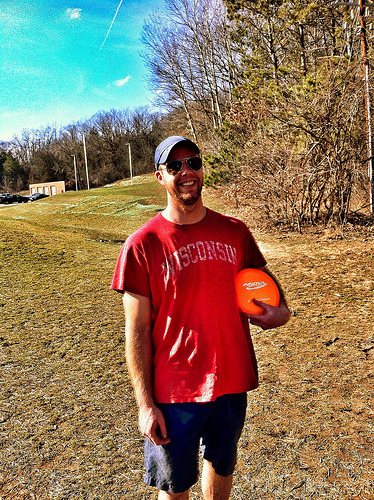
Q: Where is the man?
A: Grass field.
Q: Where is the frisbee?
A: Man's left hand.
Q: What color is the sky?
A: Blue.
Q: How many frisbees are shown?
A: 1.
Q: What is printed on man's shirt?
A: Wisconsin.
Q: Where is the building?
A: Near cars.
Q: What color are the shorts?
A: Blue.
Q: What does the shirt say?
A: Wisconsin.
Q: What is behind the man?
A: Trees.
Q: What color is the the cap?
A: Blue.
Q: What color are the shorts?
A: Blue.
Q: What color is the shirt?
A: Red.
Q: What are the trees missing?
A: Leaves.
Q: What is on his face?
A: Glasses.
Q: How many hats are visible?
A: Just one.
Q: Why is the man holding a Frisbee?
A: It is there to play a game with.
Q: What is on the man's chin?
A: A beard.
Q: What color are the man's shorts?
A: Blue.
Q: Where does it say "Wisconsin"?
A: On the red shirt.